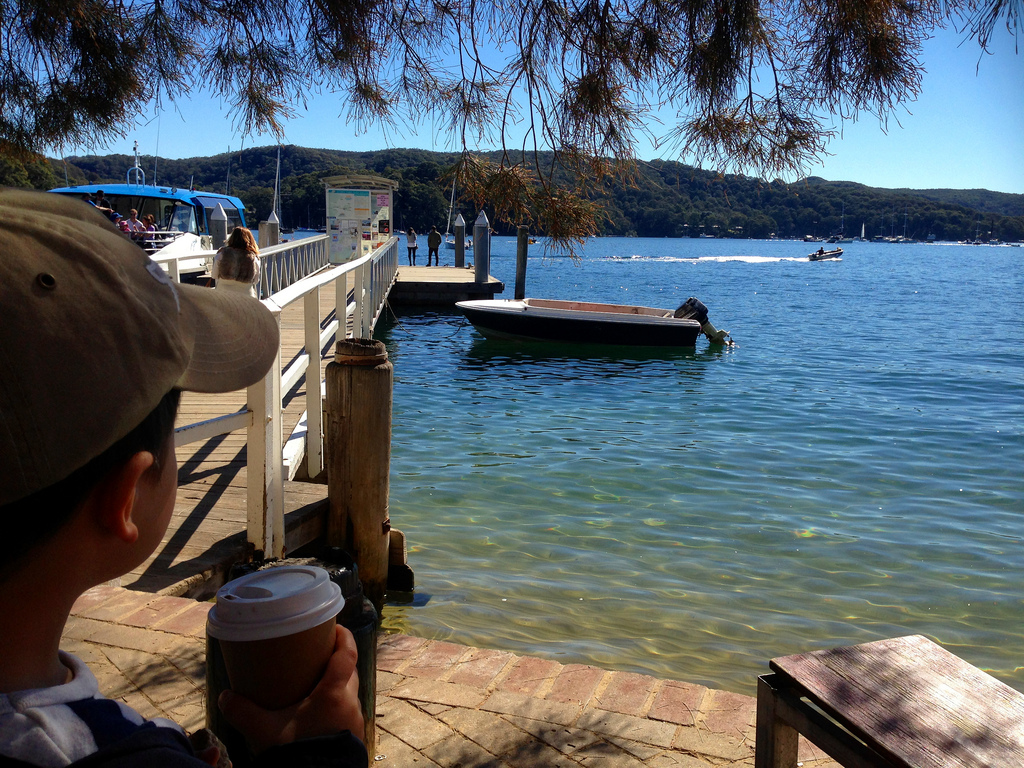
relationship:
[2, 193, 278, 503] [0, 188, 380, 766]
baseball hat on man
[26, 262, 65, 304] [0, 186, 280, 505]
hole on top of baseball hat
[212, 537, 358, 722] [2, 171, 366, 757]
cup held by man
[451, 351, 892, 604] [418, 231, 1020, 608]
ripples in water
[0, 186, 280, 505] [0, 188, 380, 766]
baseball hat worn by man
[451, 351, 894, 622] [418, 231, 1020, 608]
ripples in water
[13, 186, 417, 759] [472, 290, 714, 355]
man watching boat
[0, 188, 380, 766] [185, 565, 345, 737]
man holding cup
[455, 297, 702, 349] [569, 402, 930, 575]
boat in lake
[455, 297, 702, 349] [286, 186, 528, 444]
boat near dock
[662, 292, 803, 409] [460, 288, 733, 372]
motor on boat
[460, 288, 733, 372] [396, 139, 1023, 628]
boat in lake